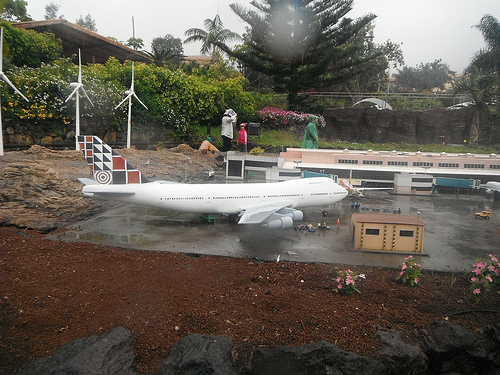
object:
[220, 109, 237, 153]
man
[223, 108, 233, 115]
hat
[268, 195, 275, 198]
window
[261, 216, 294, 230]
engine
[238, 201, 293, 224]
wing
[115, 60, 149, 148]
wind mill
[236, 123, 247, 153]
person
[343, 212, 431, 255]
building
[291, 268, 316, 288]
rock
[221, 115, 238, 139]
coat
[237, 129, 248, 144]
shirt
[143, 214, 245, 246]
asphalt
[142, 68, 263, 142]
bush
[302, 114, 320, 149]
suit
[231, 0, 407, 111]
tree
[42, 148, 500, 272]
airport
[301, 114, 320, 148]
people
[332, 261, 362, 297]
flower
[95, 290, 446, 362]
mulch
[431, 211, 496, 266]
puddle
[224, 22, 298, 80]
leaves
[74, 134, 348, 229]
airplane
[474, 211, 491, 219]
car